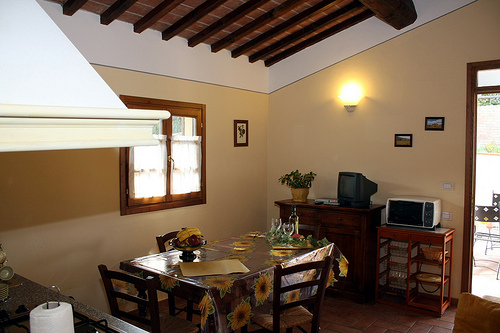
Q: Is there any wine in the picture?
A: Yes, there is wine.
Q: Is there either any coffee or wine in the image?
A: Yes, there is wine.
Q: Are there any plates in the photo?
A: No, there are no plates.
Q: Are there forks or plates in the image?
A: No, there are no plates or forks.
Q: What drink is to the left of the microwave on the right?
A: The drink is wine.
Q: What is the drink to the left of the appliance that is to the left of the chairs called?
A: The drink is wine.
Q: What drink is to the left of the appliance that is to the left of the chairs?
A: The drink is wine.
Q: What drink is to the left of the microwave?
A: The drink is wine.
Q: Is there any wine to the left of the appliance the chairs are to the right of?
A: Yes, there is wine to the left of the microwave.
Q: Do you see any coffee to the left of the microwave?
A: No, there is wine to the left of the microwave.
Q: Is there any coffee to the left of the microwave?
A: No, there is wine to the left of the microwave.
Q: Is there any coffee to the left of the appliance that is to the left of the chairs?
A: No, there is wine to the left of the microwave.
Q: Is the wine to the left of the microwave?
A: Yes, the wine is to the left of the microwave.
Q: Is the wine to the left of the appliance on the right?
A: Yes, the wine is to the left of the microwave.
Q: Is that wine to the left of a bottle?
A: No, the wine is to the left of the microwave.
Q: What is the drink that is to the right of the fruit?
A: The drink is wine.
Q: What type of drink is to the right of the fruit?
A: The drink is wine.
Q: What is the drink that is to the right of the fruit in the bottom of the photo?
A: The drink is wine.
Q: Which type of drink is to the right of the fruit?
A: The drink is wine.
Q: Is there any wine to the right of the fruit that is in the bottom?
A: Yes, there is wine to the right of the fruit.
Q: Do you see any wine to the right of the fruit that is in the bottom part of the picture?
A: Yes, there is wine to the right of the fruit.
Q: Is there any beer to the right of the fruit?
A: No, there is wine to the right of the fruit.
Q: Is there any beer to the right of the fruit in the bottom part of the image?
A: No, there is wine to the right of the fruit.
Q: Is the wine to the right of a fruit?
A: Yes, the wine is to the right of a fruit.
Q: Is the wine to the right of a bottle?
A: No, the wine is to the right of a fruit.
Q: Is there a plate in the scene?
A: No, there are no plates.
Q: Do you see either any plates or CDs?
A: No, there are no plates or cds.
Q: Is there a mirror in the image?
A: No, there are no mirrors.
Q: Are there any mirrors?
A: No, there are no mirrors.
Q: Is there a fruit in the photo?
A: Yes, there is a fruit.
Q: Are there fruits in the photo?
A: Yes, there is a fruit.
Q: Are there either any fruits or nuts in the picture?
A: Yes, there is a fruit.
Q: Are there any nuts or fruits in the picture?
A: Yes, there is a fruit.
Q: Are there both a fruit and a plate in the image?
A: No, there is a fruit but no plates.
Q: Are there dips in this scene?
A: No, there are no dips.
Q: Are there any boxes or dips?
A: No, there are no dips or boxes.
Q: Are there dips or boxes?
A: No, there are no dips or boxes.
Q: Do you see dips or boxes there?
A: No, there are no dips or boxes.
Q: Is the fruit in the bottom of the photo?
A: Yes, the fruit is in the bottom of the image.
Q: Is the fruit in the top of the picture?
A: No, the fruit is in the bottom of the image.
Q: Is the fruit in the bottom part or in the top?
A: The fruit is in the bottom of the image.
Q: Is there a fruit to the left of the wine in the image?
A: Yes, there is a fruit to the left of the wine.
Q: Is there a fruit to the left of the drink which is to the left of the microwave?
A: Yes, there is a fruit to the left of the wine.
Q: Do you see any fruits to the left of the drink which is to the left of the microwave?
A: Yes, there is a fruit to the left of the wine.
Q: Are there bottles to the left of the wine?
A: No, there is a fruit to the left of the wine.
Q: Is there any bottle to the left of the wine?
A: No, there is a fruit to the left of the wine.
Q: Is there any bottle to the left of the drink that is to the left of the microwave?
A: No, there is a fruit to the left of the wine.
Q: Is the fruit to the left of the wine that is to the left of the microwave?
A: Yes, the fruit is to the left of the wine.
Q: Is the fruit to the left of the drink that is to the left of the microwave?
A: Yes, the fruit is to the left of the wine.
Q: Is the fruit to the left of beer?
A: No, the fruit is to the left of the wine.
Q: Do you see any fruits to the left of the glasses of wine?
A: Yes, there is a fruit to the left of the glasses.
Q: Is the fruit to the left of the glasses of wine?
A: Yes, the fruit is to the left of the glasses.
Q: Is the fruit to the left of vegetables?
A: No, the fruit is to the left of the glasses.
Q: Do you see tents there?
A: No, there are no tents.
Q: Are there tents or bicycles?
A: No, there are no tents or bicycles.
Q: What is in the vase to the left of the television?
A: The plant is in the vase.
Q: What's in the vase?
A: The plant is in the vase.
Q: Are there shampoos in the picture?
A: No, there are no shampoos.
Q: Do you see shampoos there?
A: No, there are no shampoos.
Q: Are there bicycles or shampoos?
A: No, there are no shampoos or bicycles.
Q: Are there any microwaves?
A: Yes, there is a microwave.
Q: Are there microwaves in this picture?
A: Yes, there is a microwave.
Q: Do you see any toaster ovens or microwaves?
A: Yes, there is a microwave.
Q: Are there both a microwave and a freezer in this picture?
A: No, there is a microwave but no refrigerators.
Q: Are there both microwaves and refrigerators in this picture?
A: No, there is a microwave but no refrigerators.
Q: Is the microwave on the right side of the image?
A: Yes, the microwave is on the right of the image.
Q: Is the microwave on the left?
A: No, the microwave is on the right of the image.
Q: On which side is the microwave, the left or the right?
A: The microwave is on the right of the image.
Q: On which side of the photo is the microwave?
A: The microwave is on the right of the image.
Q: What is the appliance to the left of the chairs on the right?
A: The appliance is a microwave.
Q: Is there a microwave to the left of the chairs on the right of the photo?
A: Yes, there is a microwave to the left of the chairs.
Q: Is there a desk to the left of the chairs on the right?
A: No, there is a microwave to the left of the chairs.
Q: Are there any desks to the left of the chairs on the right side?
A: No, there is a microwave to the left of the chairs.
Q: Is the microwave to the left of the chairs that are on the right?
A: Yes, the microwave is to the left of the chairs.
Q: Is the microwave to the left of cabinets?
A: No, the microwave is to the left of the chairs.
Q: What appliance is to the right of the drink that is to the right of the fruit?
A: The appliance is a microwave.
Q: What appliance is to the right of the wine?
A: The appliance is a microwave.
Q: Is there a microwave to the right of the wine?
A: Yes, there is a microwave to the right of the wine.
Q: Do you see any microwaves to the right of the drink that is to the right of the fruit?
A: Yes, there is a microwave to the right of the wine.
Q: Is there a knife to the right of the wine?
A: No, there is a microwave to the right of the wine.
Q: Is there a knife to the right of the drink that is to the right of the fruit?
A: No, there is a microwave to the right of the wine.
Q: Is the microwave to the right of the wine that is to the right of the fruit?
A: Yes, the microwave is to the right of the wine.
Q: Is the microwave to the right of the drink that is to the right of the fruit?
A: Yes, the microwave is to the right of the wine.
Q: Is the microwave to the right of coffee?
A: No, the microwave is to the right of the wine.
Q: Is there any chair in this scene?
A: Yes, there is a chair.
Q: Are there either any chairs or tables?
A: Yes, there is a chair.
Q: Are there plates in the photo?
A: No, there are no plates.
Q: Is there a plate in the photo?
A: No, there are no plates.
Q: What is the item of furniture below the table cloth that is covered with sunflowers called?
A: The piece of furniture is a chair.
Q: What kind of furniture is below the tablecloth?
A: The piece of furniture is a chair.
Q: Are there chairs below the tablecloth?
A: Yes, there is a chair below the tablecloth.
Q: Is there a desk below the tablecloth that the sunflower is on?
A: No, there is a chair below the tablecloth.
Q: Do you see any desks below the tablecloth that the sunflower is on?
A: No, there is a chair below the tablecloth.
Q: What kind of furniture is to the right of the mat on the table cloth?
A: The piece of furniture is a chair.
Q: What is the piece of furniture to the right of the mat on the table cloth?
A: The piece of furniture is a chair.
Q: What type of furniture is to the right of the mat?
A: The piece of furniture is a chair.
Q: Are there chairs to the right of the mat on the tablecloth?
A: Yes, there is a chair to the right of the mat.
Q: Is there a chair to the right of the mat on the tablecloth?
A: Yes, there is a chair to the right of the mat.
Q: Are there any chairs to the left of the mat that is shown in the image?
A: No, the chair is to the right of the mat.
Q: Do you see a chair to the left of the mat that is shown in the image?
A: No, the chair is to the right of the mat.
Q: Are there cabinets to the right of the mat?
A: No, there is a chair to the right of the mat.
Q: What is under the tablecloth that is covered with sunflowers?
A: The chair is under the tablecloth.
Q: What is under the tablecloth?
A: The chair is under the tablecloth.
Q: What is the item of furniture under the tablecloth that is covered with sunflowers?
A: The piece of furniture is a chair.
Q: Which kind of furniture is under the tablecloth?
A: The piece of furniture is a chair.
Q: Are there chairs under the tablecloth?
A: Yes, there is a chair under the tablecloth.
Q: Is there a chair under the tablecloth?
A: Yes, there is a chair under the tablecloth.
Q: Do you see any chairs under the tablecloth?
A: Yes, there is a chair under the tablecloth.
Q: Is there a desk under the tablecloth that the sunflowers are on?
A: No, there is a chair under the tablecloth.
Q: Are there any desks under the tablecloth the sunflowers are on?
A: No, there is a chair under the tablecloth.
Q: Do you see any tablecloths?
A: Yes, there is a tablecloth.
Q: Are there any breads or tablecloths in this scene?
A: Yes, there is a tablecloth.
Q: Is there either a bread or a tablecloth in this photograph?
A: Yes, there is a tablecloth.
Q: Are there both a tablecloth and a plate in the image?
A: No, there is a tablecloth but no plates.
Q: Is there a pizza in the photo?
A: No, there are no pizzas.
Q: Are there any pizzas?
A: No, there are no pizzas.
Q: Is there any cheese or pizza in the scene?
A: No, there are no pizzas or cheese.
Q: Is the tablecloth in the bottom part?
A: Yes, the tablecloth is in the bottom of the image.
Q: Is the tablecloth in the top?
A: No, the tablecloth is in the bottom of the image.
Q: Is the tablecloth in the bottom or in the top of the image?
A: The tablecloth is in the bottom of the image.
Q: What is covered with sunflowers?
A: The table cloth is covered with sunflowers.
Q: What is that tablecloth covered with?
A: The tablecloth is covered with sunflowers.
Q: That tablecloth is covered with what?
A: The tablecloth is covered with sunflowers.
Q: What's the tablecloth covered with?
A: The tablecloth is covered with sunflowers.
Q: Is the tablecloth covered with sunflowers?
A: Yes, the tablecloth is covered with sunflowers.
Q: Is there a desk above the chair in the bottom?
A: No, there is a tablecloth above the chair.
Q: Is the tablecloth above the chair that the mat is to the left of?
A: Yes, the tablecloth is above the chair.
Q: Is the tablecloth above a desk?
A: No, the tablecloth is above the chair.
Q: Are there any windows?
A: Yes, there is a window.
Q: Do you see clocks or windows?
A: Yes, there is a window.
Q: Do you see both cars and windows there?
A: No, there is a window but no cars.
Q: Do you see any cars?
A: No, there are no cars.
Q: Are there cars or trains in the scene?
A: No, there are no cars or trains.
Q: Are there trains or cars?
A: No, there are no cars or trains.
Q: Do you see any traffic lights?
A: No, there are no traffic lights.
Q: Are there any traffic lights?
A: No, there are no traffic lights.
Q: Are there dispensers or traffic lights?
A: No, there are no traffic lights or dispensers.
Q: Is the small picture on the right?
A: Yes, the picture is on the right of the image.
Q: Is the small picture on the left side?
A: No, the picture is on the right of the image.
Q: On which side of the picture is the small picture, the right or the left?
A: The picture is on the right of the image.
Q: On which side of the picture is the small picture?
A: The picture is on the right of the image.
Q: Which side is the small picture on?
A: The picture is on the right of the image.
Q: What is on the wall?
A: The picture is on the wall.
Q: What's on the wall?
A: The picture is on the wall.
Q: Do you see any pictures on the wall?
A: Yes, there is a picture on the wall.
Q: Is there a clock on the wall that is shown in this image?
A: No, there is a picture on the wall.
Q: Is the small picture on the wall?
A: Yes, the picture is on the wall.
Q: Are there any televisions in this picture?
A: Yes, there is a television.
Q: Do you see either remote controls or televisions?
A: Yes, there is a television.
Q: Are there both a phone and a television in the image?
A: No, there is a television but no phones.